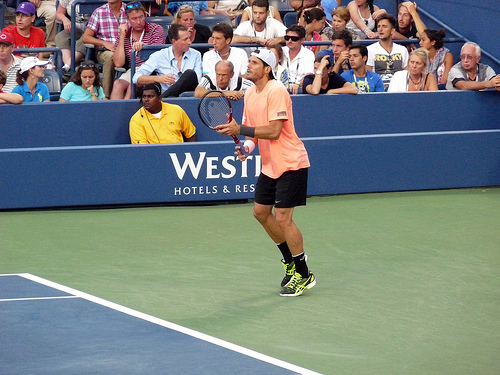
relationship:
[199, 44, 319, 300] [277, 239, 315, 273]
player wears socks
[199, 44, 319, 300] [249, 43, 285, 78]
player wearing cap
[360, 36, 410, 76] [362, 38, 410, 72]
man wears shirt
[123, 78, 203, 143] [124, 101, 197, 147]
man wears shirt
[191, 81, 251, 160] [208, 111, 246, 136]
racket in hand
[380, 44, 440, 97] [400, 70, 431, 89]
woman wears necklace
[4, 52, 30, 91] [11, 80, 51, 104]
man wears blue shirt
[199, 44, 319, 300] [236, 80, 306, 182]
player wears shirt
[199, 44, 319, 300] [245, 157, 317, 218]
player wears black shorts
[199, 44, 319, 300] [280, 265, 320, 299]
player wears shoes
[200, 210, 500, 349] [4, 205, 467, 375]
green area behind court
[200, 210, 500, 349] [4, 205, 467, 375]
green area next to court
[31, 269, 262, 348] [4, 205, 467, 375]
end of court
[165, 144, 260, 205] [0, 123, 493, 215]
writing on wall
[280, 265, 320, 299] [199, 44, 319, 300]
shoes are worn by player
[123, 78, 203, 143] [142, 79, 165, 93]
man wears headphones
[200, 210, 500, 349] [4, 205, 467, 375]
green area of court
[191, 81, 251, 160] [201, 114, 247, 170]
racket being held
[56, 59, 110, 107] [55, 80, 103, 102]
woman wears blue shirt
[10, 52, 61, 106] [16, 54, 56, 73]
woman wears white hat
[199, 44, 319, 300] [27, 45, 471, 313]
player in game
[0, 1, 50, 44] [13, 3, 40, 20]
man wears purple cap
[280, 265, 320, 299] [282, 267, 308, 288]
shoes have yellow laces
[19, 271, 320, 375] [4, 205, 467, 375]
end of court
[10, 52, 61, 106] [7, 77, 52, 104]
woman in blue shirt